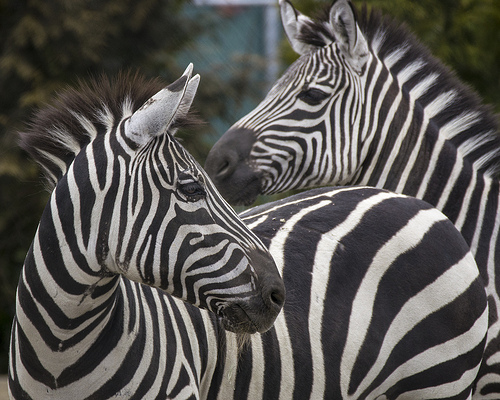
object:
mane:
[296, 0, 499, 178]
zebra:
[8, 63, 488, 400]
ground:
[0, 0, 500, 210]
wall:
[174, 0, 261, 152]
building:
[174, 0, 268, 139]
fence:
[171, 0, 279, 171]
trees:
[279, 0, 499, 115]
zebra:
[203, 0, 500, 399]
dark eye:
[297, 88, 331, 106]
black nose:
[262, 284, 286, 312]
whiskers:
[218, 321, 253, 363]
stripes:
[339, 203, 447, 400]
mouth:
[234, 301, 261, 334]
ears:
[124, 63, 194, 145]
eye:
[178, 182, 204, 196]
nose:
[211, 158, 238, 181]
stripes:
[16, 272, 62, 353]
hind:
[376, 190, 488, 343]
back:
[148, 181, 410, 241]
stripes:
[127, 131, 160, 283]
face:
[134, 132, 286, 336]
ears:
[172, 71, 200, 118]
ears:
[327, 0, 370, 60]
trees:
[0, 0, 220, 329]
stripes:
[346, 215, 473, 396]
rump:
[307, 184, 492, 388]